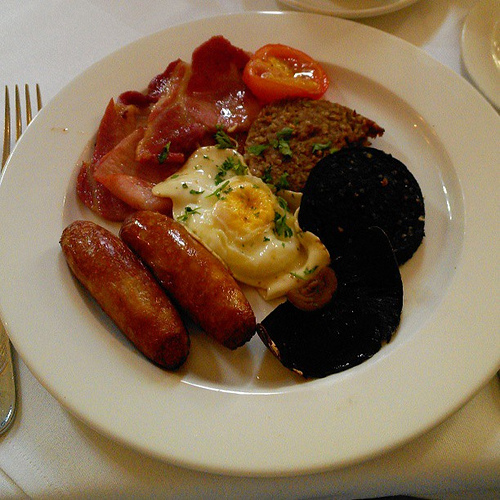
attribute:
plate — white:
[4, 9, 499, 454]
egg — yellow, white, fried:
[165, 150, 350, 293]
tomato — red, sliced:
[249, 37, 321, 106]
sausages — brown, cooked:
[54, 204, 254, 370]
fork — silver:
[4, 80, 49, 436]